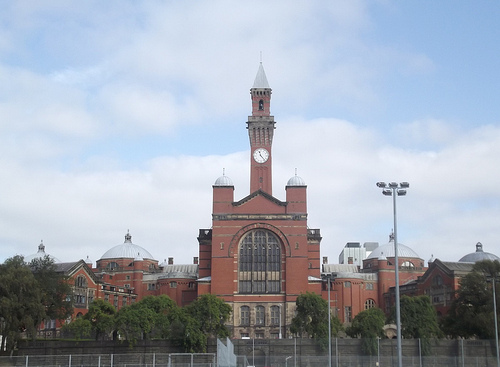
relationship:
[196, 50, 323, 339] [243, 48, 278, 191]
building has tower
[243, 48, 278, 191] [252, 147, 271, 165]
tower has clock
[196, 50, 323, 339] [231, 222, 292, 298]
building has window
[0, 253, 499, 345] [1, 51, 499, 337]
trees in front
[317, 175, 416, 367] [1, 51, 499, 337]
light in front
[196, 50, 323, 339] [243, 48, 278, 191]
large clock tower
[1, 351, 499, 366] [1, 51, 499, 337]
fence in front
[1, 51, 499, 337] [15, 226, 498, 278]
building has domes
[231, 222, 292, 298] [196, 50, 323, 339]
windows on building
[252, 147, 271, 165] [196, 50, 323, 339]
clock on tower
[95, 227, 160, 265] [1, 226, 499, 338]
dome on building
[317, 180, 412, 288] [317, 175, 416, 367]
lights on pole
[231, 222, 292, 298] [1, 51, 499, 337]
window in front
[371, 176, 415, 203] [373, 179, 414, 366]
lights on pole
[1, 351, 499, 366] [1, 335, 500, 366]
fence in foreground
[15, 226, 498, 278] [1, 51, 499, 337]
domes on building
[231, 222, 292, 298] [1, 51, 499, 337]
window on front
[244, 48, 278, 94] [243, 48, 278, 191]
top of tower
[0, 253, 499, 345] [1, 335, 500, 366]
trees behind wall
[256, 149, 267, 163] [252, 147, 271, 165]
hands on clock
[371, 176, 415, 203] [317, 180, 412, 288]
these bright lights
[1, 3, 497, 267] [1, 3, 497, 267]
clouds in daytime sky